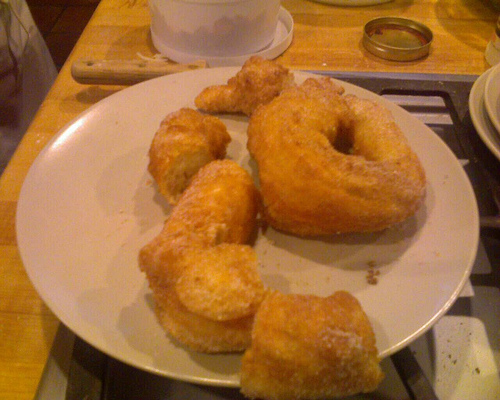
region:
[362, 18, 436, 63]
gold plastic bottle cap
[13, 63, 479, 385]
round white ceramic plate on table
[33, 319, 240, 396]
placemat under white plate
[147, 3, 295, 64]
white plastic container on table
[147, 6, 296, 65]
white plastic lid under container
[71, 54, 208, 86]
wooden knife hnadle next to plate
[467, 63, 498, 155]
plate visible to the right of plate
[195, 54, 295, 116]
small piece of doughnut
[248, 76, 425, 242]
round doughnut on top of plate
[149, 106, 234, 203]
piece of doughnut next to piece of doughnut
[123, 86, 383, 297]
food on a plate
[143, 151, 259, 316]
white sugar on the food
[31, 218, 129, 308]
white plate under food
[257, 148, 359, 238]
brown food with sugar on it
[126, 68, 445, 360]
many pieces of food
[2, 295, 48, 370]
brown table next to food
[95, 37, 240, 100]
knife next to plate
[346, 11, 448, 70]
can next to plate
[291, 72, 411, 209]
hole in middle of food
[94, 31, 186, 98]
handle of a knife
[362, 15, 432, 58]
lid on wooden counter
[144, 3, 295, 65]
white plastic lid under plastic container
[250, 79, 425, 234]
a whole donut on a plate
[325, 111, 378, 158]
a donut hole in a donut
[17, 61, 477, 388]
a plate of donut pieces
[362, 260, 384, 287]
crumbs on a white plate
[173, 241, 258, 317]
broken surface of a donut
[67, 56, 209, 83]
wooden handle of a knife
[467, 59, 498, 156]
couple of plates on the right of photo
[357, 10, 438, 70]
a mason jar lid on the counter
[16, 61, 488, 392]
The plate is round.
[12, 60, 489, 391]
The plate is white.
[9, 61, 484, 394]
The plate is being utilized.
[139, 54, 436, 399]
The donuts are various shapes.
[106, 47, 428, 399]
The donuts appear to be homemade.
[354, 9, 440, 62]
There is a lid on the counter.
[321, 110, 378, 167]
The donut has a hole.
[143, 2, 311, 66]
The container is sitting on the lid.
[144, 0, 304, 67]
The container is white.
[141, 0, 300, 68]
The container is plastic.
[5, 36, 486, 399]
white plate with food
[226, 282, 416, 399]
a piece of food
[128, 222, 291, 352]
a piece of food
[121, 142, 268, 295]
a piece of food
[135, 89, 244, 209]
a piece of food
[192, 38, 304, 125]
a piece of food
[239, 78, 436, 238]
a piece of food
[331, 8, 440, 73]
metal lid to a jar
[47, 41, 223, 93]
a wooden knife handle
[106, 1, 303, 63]
plastic container and lid